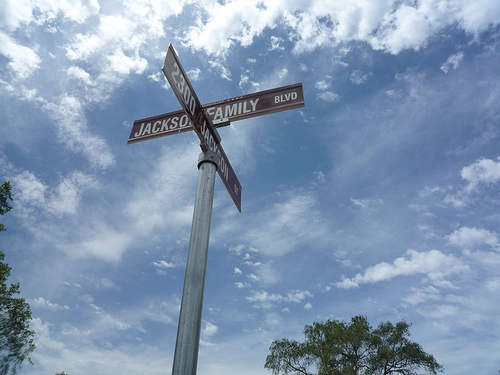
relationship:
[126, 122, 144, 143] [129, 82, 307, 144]
alphabet on plate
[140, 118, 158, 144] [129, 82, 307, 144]
alphabet on plate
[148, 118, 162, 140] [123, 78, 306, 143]
alphabet on plate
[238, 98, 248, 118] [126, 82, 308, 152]
alphabet on plate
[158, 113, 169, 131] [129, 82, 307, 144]
alphabet on plate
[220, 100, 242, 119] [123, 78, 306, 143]
alphabet on plate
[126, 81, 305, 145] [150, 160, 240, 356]
sign on pole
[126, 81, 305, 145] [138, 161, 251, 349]
sign on pole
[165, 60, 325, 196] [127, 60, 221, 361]
sign on pole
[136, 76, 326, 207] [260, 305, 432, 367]
sign by tree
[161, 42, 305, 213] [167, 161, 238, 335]
sign on post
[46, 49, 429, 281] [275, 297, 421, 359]
sky above trees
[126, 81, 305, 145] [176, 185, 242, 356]
sign on pole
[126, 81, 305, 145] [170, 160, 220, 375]
sign on pole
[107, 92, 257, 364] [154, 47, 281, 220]
pole holds sign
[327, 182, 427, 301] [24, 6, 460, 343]
clouds in sky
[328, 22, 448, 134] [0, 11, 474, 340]
clouds in sky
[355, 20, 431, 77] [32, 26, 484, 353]
clouds in sky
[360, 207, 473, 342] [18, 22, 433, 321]
clouds in sky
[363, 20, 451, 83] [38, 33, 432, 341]
clouds in sky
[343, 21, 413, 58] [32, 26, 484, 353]
clouds in sky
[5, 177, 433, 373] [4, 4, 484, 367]
trees under sky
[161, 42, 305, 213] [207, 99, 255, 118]
sign with letters